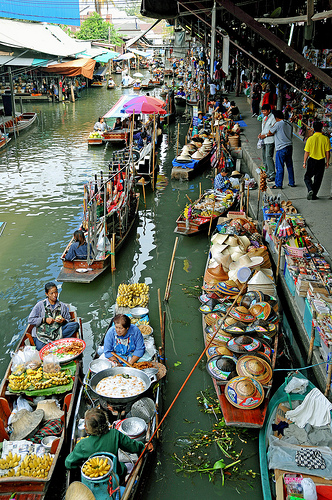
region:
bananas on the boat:
[107, 282, 156, 313]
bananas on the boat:
[3, 447, 59, 476]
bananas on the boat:
[9, 363, 86, 391]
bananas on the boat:
[75, 453, 113, 483]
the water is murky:
[169, 289, 191, 346]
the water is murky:
[119, 236, 165, 284]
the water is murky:
[11, 201, 49, 273]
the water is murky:
[170, 363, 217, 418]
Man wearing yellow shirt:
[299, 127, 330, 163]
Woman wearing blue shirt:
[101, 320, 151, 367]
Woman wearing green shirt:
[62, 429, 147, 480]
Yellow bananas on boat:
[2, 363, 76, 395]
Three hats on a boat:
[208, 351, 275, 416]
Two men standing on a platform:
[250, 102, 302, 193]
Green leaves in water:
[187, 431, 236, 479]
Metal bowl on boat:
[81, 360, 159, 403]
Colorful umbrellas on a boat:
[116, 92, 172, 125]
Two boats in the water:
[2, 279, 174, 497]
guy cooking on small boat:
[104, 315, 150, 366]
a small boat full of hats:
[199, 213, 278, 410]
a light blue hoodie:
[102, 322, 142, 354]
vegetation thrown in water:
[174, 388, 252, 479]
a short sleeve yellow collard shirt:
[305, 132, 329, 159]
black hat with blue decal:
[206, 352, 235, 380]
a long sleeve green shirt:
[63, 428, 146, 475]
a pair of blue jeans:
[273, 147, 294, 188]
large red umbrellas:
[119, 93, 166, 116]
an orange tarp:
[48, 57, 95, 79]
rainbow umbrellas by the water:
[119, 92, 168, 117]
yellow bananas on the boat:
[115, 280, 150, 307]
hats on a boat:
[198, 217, 276, 417]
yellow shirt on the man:
[302, 132, 331, 160]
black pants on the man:
[301, 154, 326, 193]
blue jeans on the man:
[271, 145, 296, 186]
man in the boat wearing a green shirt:
[64, 430, 142, 466]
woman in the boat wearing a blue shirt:
[103, 324, 147, 360]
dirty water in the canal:
[0, 91, 109, 359]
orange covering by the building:
[47, 54, 96, 85]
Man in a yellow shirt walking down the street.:
[302, 120, 330, 205]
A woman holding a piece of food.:
[21, 280, 79, 352]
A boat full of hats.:
[198, 206, 281, 425]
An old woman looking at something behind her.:
[62, 398, 157, 493]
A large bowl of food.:
[83, 361, 166, 405]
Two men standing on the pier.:
[254, 94, 300, 194]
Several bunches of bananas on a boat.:
[3, 346, 78, 403]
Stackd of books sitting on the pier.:
[282, 242, 331, 379]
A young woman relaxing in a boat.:
[57, 157, 140, 281]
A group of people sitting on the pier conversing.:
[206, 89, 246, 126]